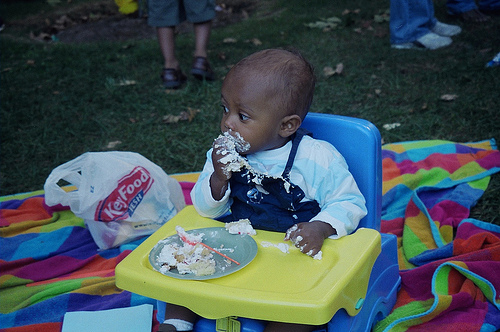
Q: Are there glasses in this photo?
A: No, there are no glasses.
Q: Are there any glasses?
A: No, there are no glasses.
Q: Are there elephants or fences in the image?
A: No, there are no fences or elephants.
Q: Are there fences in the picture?
A: No, there are no fences.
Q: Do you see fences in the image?
A: No, there are no fences.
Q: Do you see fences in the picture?
A: No, there are no fences.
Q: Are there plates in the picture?
A: Yes, there is a plate.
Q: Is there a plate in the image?
A: Yes, there is a plate.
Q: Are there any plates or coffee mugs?
A: Yes, there is a plate.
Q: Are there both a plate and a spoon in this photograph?
A: No, there is a plate but no spoons.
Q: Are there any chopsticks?
A: No, there are no chopsticks.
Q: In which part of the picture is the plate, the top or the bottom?
A: The plate is in the bottom of the image.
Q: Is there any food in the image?
A: Yes, there is food.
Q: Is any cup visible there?
A: No, there are no cups.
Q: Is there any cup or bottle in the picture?
A: No, there are no cups or bottles.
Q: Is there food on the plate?
A: Yes, there is food on the plate.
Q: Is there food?
A: Yes, there is food.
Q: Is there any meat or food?
A: Yes, there is food.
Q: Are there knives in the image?
A: No, there are no knives.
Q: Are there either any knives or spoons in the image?
A: No, there are no knives or spoons.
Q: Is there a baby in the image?
A: Yes, there is a baby.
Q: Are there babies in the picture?
A: Yes, there is a baby.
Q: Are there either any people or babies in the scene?
A: Yes, there is a baby.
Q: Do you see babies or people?
A: Yes, there is a baby.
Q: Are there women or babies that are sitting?
A: Yes, the baby is sitting.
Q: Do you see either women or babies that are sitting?
A: Yes, the baby is sitting.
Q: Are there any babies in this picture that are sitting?
A: Yes, there is a baby that is sitting.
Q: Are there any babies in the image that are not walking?
A: Yes, there is a baby that is sitting.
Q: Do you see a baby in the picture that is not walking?
A: Yes, there is a baby that is sitting .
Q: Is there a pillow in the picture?
A: No, there are no pillows.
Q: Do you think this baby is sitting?
A: Yes, the baby is sitting.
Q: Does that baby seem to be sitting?
A: Yes, the baby is sitting.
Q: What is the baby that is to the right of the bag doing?
A: The baby is sitting.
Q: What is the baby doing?
A: The baby is sitting.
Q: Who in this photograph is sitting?
A: The baby is sitting.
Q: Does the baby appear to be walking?
A: No, the baby is sitting.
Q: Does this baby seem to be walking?
A: No, the baby is sitting.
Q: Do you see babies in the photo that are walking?
A: No, there is a baby but he is sitting.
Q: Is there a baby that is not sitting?
A: No, there is a baby but he is sitting.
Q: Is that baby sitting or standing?
A: The baby is sitting.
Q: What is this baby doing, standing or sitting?
A: The baby is sitting.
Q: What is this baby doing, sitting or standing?
A: The baby is sitting.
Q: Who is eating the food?
A: The baby is eating the food.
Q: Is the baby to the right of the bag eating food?
A: Yes, the baby is eating food.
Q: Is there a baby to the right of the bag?
A: Yes, there is a baby to the right of the bag.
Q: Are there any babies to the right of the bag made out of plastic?
A: Yes, there is a baby to the right of the bag.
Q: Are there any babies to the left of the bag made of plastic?
A: No, the baby is to the right of the bag.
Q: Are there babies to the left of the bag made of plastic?
A: No, the baby is to the right of the bag.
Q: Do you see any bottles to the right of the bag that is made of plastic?
A: No, there is a baby to the right of the bag.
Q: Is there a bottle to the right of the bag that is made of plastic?
A: No, there is a baby to the right of the bag.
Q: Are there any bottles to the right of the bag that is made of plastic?
A: No, there is a baby to the right of the bag.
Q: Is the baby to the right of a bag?
A: Yes, the baby is to the right of a bag.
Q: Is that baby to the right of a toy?
A: No, the baby is to the right of a bag.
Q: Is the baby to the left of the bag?
A: No, the baby is to the right of the bag.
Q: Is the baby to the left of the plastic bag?
A: No, the baby is to the right of the bag.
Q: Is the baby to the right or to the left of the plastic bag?
A: The baby is to the right of the bag.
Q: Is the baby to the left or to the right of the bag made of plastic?
A: The baby is to the right of the bag.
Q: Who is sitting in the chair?
A: The baby is sitting in the chair.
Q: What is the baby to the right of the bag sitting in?
A: The baby is sitting in the chair.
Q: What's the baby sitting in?
A: The baby is sitting in the chair.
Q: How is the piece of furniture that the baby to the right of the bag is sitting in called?
A: The piece of furniture is a chair.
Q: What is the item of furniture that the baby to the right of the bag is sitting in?
A: The piece of furniture is a chair.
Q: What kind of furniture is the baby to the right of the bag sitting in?
A: The baby is sitting in the chair.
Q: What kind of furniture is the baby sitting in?
A: The baby is sitting in the chair.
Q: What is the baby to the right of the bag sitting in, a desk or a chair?
A: The baby is sitting in a chair.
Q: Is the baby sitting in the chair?
A: Yes, the baby is sitting in the chair.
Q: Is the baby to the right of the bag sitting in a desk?
A: No, the baby is sitting in the chair.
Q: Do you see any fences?
A: No, there are no fences.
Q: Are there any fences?
A: No, there are no fences.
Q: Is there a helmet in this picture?
A: No, there are no helmets.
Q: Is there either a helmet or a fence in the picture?
A: No, there are no helmets or fences.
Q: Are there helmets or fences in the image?
A: No, there are no helmets or fences.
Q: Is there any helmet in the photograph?
A: No, there are no helmets.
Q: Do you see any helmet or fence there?
A: No, there are no helmets or fences.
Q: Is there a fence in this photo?
A: No, there are no fences.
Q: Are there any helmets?
A: No, there are no helmets.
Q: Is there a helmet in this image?
A: No, there are no helmets.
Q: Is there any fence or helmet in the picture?
A: No, there are no helmets or fences.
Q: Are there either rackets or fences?
A: No, there are no fences or rackets.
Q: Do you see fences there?
A: No, there are no fences.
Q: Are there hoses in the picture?
A: No, there are no hoses.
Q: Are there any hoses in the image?
A: No, there are no hoses.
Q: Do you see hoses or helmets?
A: No, there are no hoses or helmets.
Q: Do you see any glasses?
A: No, there are no glasses.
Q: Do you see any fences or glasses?
A: No, there are no glasses or fences.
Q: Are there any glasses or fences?
A: No, there are no glasses or fences.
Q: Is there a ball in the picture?
A: No, there are no balls.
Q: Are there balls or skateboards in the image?
A: No, there are no balls or skateboards.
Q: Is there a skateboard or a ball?
A: No, there are no balls or skateboards.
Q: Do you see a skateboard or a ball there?
A: No, there are no balls or skateboards.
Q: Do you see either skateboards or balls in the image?
A: No, there are no balls or skateboards.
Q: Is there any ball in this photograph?
A: No, there are no balls.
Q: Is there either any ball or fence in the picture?
A: No, there are no balls or fences.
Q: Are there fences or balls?
A: No, there are no balls or fences.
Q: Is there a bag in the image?
A: Yes, there is a bag.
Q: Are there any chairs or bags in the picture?
A: Yes, there is a bag.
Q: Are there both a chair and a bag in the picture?
A: Yes, there are both a bag and a chair.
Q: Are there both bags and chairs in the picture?
A: Yes, there are both a bag and a chair.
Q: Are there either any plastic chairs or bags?
A: Yes, there is a plastic bag.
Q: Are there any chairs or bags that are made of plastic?
A: Yes, the bag is made of plastic.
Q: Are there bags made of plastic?
A: Yes, there is a bag that is made of plastic.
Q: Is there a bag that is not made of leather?
A: Yes, there is a bag that is made of plastic.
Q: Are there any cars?
A: No, there are no cars.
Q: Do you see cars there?
A: No, there are no cars.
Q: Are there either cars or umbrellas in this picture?
A: No, there are no cars or umbrellas.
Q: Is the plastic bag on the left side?
A: Yes, the bag is on the left of the image.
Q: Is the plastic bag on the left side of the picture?
A: Yes, the bag is on the left of the image.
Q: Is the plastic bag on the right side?
A: No, the bag is on the left of the image.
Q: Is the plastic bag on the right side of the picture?
A: No, the bag is on the left of the image.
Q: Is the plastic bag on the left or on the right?
A: The bag is on the left of the image.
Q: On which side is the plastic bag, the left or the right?
A: The bag is on the left of the image.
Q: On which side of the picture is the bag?
A: The bag is on the left of the image.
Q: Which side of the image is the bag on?
A: The bag is on the left of the image.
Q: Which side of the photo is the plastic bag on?
A: The bag is on the left of the image.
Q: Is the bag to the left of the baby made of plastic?
A: Yes, the bag is made of plastic.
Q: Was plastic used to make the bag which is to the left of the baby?
A: Yes, the bag is made of plastic.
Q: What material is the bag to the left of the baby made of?
A: The bag is made of plastic.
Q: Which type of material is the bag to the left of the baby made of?
A: The bag is made of plastic.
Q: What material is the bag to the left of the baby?
A: The bag is made of plastic.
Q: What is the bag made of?
A: The bag is made of plastic.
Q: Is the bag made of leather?
A: No, the bag is made of plastic.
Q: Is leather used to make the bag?
A: No, the bag is made of plastic.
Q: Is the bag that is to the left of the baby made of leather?
A: No, the bag is made of plastic.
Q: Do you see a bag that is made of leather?
A: No, there is a bag but it is made of plastic.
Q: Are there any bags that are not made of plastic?
A: No, there is a bag but it is made of plastic.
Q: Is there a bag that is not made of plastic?
A: No, there is a bag but it is made of plastic.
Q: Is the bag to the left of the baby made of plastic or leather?
A: The bag is made of plastic.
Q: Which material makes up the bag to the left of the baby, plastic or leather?
A: The bag is made of plastic.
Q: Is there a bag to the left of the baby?
A: Yes, there is a bag to the left of the baby.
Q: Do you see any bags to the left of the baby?
A: Yes, there is a bag to the left of the baby.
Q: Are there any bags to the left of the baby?
A: Yes, there is a bag to the left of the baby.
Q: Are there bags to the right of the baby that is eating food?
A: No, the bag is to the left of the baby.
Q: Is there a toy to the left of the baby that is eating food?
A: No, there is a bag to the left of the baby.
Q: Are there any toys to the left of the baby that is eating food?
A: No, there is a bag to the left of the baby.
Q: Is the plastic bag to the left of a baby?
A: Yes, the bag is to the left of a baby.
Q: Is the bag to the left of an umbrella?
A: No, the bag is to the left of a baby.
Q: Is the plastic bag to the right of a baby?
A: No, the bag is to the left of a baby.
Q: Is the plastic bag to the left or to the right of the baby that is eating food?
A: The bag is to the left of the baby.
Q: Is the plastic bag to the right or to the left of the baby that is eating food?
A: The bag is to the left of the baby.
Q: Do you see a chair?
A: Yes, there is a chair.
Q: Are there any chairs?
A: Yes, there is a chair.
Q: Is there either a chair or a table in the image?
A: Yes, there is a chair.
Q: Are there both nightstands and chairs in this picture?
A: No, there is a chair but no nightstands.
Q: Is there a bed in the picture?
A: No, there are no beds.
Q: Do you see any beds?
A: No, there are no beds.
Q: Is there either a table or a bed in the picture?
A: No, there are no beds or tables.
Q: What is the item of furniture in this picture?
A: The piece of furniture is a chair.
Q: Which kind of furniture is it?
A: The piece of furniture is a chair.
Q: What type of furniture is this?
A: That is a chair.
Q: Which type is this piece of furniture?
A: That is a chair.